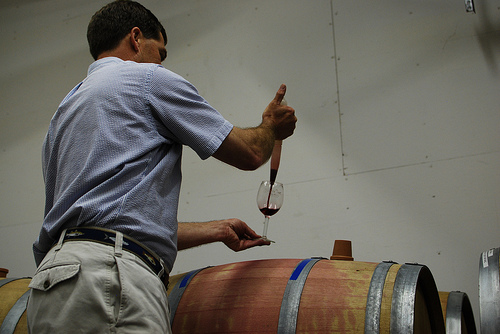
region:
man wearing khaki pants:
[28, 234, 175, 331]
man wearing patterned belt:
[19, 231, 186, 270]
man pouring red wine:
[231, 80, 311, 257]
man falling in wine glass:
[246, 155, 295, 249]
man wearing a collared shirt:
[21, 52, 237, 235]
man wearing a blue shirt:
[37, 66, 242, 231]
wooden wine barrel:
[177, 249, 493, 331]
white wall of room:
[327, 18, 464, 183]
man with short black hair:
[76, 8, 188, 68]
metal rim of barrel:
[389, 249, 439, 329]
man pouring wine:
[20, 2, 300, 327]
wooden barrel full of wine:
[153, 240, 457, 331]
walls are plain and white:
[5, 3, 495, 310]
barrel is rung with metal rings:
[170, 260, 445, 327]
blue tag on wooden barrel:
[284, 242, 316, 286]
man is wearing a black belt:
[30, 218, 171, 284]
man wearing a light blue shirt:
[33, 50, 238, 250]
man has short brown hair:
[74, 2, 172, 62]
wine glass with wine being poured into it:
[250, 150, 290, 244]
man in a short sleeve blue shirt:
[33, 0, 248, 325]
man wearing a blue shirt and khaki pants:
[13, 6, 175, 328]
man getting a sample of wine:
[16, 9, 339, 246]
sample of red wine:
[237, 85, 317, 252]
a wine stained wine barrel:
[182, 255, 459, 332]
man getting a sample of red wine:
[188, 61, 348, 258]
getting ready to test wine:
[66, 5, 371, 266]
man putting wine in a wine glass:
[227, 71, 343, 266]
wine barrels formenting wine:
[179, 221, 497, 332]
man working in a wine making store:
[11, 3, 406, 318]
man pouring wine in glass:
[241, 65, 303, 255]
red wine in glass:
[252, 195, 292, 220]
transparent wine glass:
[258, 180, 286, 218]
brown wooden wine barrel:
[171, 249, 419, 331]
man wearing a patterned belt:
[46, 220, 186, 279]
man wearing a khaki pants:
[13, 229, 189, 329]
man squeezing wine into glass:
[257, 77, 308, 261]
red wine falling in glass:
[259, 175, 286, 207]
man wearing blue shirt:
[25, 26, 245, 261]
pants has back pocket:
[17, 247, 89, 312]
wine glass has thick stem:
[250, 151, 282, 251]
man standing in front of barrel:
[14, 8, 444, 329]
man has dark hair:
[67, 4, 176, 56]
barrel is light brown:
[163, 245, 433, 332]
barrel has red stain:
[162, 238, 389, 328]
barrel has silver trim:
[165, 241, 451, 324]